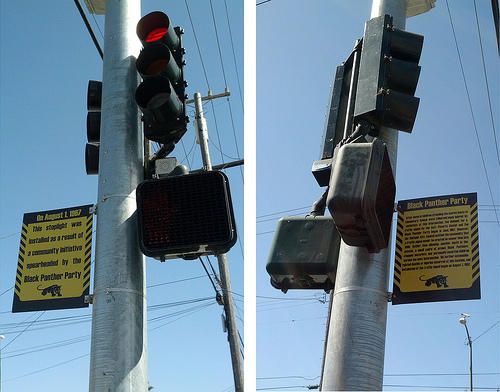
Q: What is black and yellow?
A: Sign.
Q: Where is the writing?
A: On sign.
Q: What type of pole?
A: Power.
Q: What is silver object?
A: Pole.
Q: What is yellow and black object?
A: Sign.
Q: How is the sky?
A: Clear.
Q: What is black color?
A: Light.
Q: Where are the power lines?
A: In sky.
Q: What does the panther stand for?
A: Black Panther Party.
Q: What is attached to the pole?
A: A stoplight.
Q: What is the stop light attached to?
A: A pole.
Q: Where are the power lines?
A: Above the stoplight.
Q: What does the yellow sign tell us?
A: The stoplight is dedicated to the black panther party.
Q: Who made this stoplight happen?
A: The community.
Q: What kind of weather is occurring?
A: Sunny skies.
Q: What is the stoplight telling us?
A: To stop.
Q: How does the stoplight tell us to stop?
A: The red light comes on.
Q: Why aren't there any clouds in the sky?
A: It's a clear sky.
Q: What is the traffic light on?
A: A metal pole.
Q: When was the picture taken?
A: Daytime.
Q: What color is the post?
A: Silver.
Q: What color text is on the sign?
A: Black.